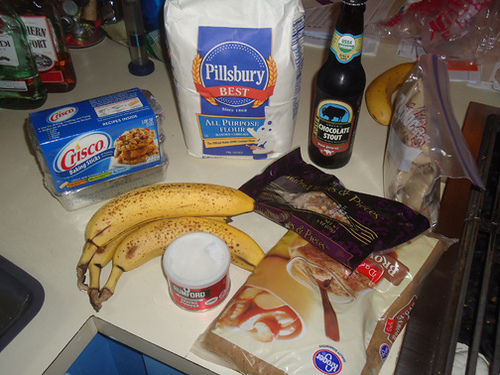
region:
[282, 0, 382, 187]
a bottle of alcohol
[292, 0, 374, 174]
a glass bottle of beer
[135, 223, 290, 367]
a container of baking powder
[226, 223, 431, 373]
a bag of brown sugar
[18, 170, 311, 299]
three ripe bananas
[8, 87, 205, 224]
a container of crisco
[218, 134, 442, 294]
a bag of walnuts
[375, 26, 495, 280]
a ziplock bag on a counter top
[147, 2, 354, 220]
a white bag of flour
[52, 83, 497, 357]
a white counter top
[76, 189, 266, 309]
banana on the counter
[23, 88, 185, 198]
crisco oil on top of the counter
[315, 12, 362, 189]
bottle of beer on the counter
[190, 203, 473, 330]
brown sugar on the counter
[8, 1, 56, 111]
bottle of liqour on the counter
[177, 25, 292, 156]
bag of flour on the counter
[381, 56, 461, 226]
ziplock bag on the counter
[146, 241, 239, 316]
baking powder on the counter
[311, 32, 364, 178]
beer bottle on the counter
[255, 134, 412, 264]
bag of nuts on the counter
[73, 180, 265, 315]
yellow bananas with brown spots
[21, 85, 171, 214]
a container of crisco baking sticks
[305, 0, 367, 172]
a bottle of organic chocolate stout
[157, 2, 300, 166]
a bag of pillsbury all purpose flour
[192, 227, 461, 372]
a bag of kroger brand brown sugar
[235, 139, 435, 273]
a bag of pecan pieces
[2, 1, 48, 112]
a container of bacardi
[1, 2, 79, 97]
a container of southern comfort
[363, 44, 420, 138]
a banana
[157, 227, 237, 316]
a container of baking powder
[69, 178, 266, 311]
yellow banana on a counter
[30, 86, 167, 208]
a package on a counter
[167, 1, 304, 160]
a bag of flour on a counter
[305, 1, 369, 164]
a brown bottle on a counter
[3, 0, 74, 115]
clear glass bottles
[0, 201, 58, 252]
a white counter top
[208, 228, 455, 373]
a bag of brown sugar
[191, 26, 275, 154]
a label on a bag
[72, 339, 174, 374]
a blue cabinet under the counter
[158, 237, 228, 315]
a red can on a counter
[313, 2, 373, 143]
this is a bottle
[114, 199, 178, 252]
the banana are yellow in color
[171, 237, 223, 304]
this is a container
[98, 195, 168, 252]
the banana are ripe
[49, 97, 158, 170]
the box is blue in color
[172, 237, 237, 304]
the tin is short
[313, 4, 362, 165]
Beer in a bottle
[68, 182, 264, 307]
Bananas on a counter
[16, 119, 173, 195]
Crisco on the counter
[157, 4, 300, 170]
Flour in a bag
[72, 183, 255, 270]
the banana is yellow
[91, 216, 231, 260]
the banana is yellow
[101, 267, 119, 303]
stem of the banana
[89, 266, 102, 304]
stem of the banana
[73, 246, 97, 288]
stem of the banana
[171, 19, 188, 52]
the bag is white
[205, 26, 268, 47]
the bag is partly blue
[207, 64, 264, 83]
the text is white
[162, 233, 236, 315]
a jar of food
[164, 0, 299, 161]
a bag of flour